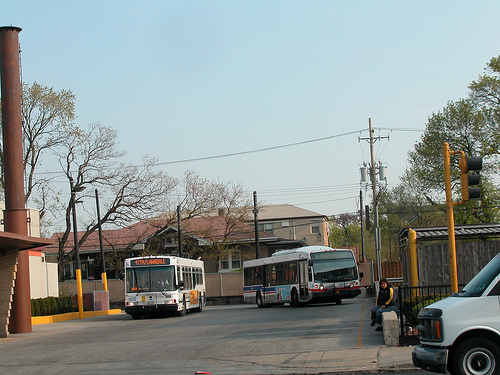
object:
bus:
[124, 254, 208, 320]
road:
[1, 289, 500, 375]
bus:
[242, 245, 361, 308]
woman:
[370, 279, 396, 333]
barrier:
[381, 310, 402, 347]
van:
[411, 251, 500, 375]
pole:
[441, 140, 461, 296]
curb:
[31, 308, 122, 327]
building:
[0, 200, 60, 300]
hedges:
[29, 298, 36, 317]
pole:
[367, 117, 385, 281]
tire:
[446, 335, 499, 375]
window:
[311, 220, 320, 234]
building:
[150, 203, 330, 248]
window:
[257, 222, 274, 234]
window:
[219, 249, 242, 271]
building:
[43, 206, 279, 310]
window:
[165, 234, 173, 245]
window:
[71, 261, 88, 281]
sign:
[130, 258, 170, 266]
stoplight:
[459, 150, 483, 201]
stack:
[1, 25, 33, 335]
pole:
[69, 177, 84, 319]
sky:
[0, 0, 500, 241]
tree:
[407, 99, 500, 227]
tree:
[466, 52, 499, 108]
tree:
[371, 183, 417, 263]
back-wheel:
[256, 291, 271, 308]